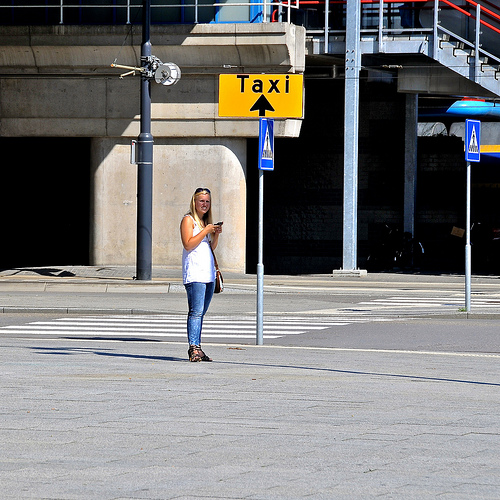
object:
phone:
[211, 220, 226, 226]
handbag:
[208, 239, 225, 296]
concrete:
[0, 341, 499, 498]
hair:
[183, 185, 214, 225]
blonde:
[179, 187, 224, 365]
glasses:
[195, 190, 210, 198]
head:
[191, 187, 212, 217]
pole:
[256, 171, 265, 346]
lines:
[0, 336, 499, 360]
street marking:
[288, 290, 499, 316]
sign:
[259, 117, 275, 174]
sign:
[462, 115, 482, 162]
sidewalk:
[0, 283, 332, 314]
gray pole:
[342, 0, 360, 271]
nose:
[200, 202, 207, 209]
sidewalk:
[0, 255, 498, 292]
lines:
[0, 327, 282, 341]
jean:
[184, 281, 215, 349]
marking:
[0, 311, 371, 352]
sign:
[217, 74, 303, 120]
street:
[0, 310, 499, 388]